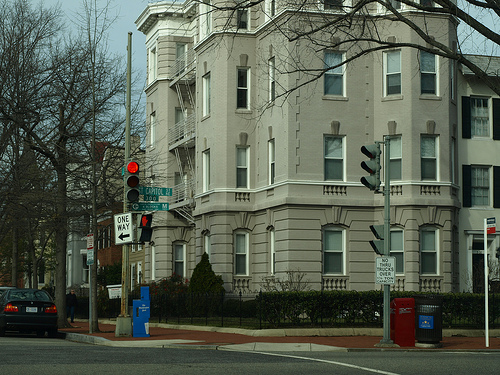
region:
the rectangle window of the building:
[320, 228, 344, 277]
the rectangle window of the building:
[233, 229, 246, 276]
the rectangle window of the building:
[389, 226, 404, 273]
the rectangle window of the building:
[421, 226, 439, 272]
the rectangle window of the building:
[235, 141, 248, 188]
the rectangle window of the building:
[266, 137, 278, 186]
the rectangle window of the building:
[324, 133, 346, 185]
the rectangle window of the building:
[385, 134, 404, 183]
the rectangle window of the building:
[420, 133, 436, 183]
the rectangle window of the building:
[472, 166, 493, 210]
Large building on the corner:
[138, 0, 498, 329]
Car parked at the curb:
[0, 287, 70, 337]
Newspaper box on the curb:
[131, 278, 152, 340]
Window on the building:
[318, 221, 348, 281]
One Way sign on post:
[113, 209, 133, 247]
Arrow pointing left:
[114, 230, 132, 243]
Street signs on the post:
[128, 181, 174, 217]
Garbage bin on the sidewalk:
[414, 298, 443, 352]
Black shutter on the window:
[461, 165, 473, 215]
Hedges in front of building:
[253, 286, 496, 331]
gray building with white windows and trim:
[131, 5, 461, 295]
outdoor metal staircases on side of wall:
[170, 45, 195, 225]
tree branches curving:
[175, 1, 495, 91]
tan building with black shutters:
[460, 56, 495, 287]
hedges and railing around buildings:
[70, 291, 490, 321]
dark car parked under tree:
[0, 5, 75, 355]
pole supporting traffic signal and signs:
[111, 30, 172, 335]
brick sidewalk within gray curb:
[80, 320, 495, 350]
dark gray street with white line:
[2, 335, 492, 370]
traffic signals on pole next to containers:
[357, 128, 443, 351]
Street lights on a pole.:
[359, 126, 399, 221]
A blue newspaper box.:
[127, 282, 160, 346]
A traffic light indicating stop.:
[118, 152, 145, 214]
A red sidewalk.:
[79, 309, 489, 354]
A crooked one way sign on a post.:
[112, 207, 135, 342]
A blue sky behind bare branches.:
[4, 3, 119, 157]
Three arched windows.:
[227, 212, 354, 289]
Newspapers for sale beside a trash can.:
[387, 292, 448, 357]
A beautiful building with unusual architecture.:
[135, 0, 460, 291]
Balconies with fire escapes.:
[169, 54, 201, 226]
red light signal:
[126, 161, 138, 173]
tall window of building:
[323, 228, 346, 275]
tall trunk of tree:
[53, 125, 71, 303]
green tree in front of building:
[188, 251, 217, 320]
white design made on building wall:
[134, 2, 177, 32]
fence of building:
[163, 291, 262, 327]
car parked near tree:
[4, 290, 56, 337]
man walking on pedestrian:
[66, 290, 78, 326]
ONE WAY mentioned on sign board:
[115, 213, 131, 243]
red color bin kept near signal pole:
[393, 297, 417, 348]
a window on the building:
[330, 138, 358, 183]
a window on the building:
[324, 232, 342, 274]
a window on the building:
[390, 219, 407, 267]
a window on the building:
[418, 233, 432, 278]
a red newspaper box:
[388, 294, 418, 350]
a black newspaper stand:
[414, 303, 444, 346]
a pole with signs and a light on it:
[112, 31, 177, 338]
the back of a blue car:
[3, 286, 60, 337]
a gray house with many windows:
[133, 1, 463, 316]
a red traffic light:
[125, 159, 141, 176]